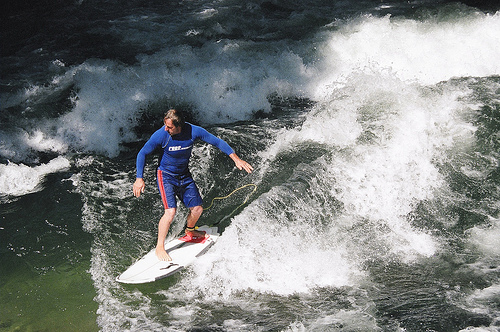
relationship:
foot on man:
[149, 252, 187, 281] [131, 108, 254, 261]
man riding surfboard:
[131, 108, 254, 261] [116, 225, 232, 281]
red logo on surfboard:
[177, 230, 205, 243] [116, 225, 217, 287]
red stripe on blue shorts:
[156, 167, 169, 208] [155, 164, 205, 209]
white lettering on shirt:
[164, 141, 194, 157] [134, 104, 237, 188]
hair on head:
[165, 107, 177, 119] [164, 106, 182, 136]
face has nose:
[151, 97, 186, 142] [161, 122, 172, 134]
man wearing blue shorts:
[131, 108, 254, 261] [155, 168, 204, 210]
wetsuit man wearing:
[135, 119, 232, 180] [132, 113, 218, 264]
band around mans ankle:
[187, 225, 199, 230] [182, 220, 201, 235]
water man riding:
[0, 0, 499, 331] [184, 171, 404, 332]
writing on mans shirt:
[166, 143, 193, 151] [134, 119, 236, 176]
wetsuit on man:
[130, 120, 236, 215] [128, 97, 261, 272]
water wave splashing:
[0, 0, 499, 331] [131, 87, 478, 332]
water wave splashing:
[0, 0, 499, 331] [175, 217, 412, 327]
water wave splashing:
[0, 0, 499, 331] [172, 187, 418, 332]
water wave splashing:
[203, 11, 488, 326] [140, 172, 443, 332]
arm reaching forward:
[192, 126, 254, 173] [114, 146, 154, 275]